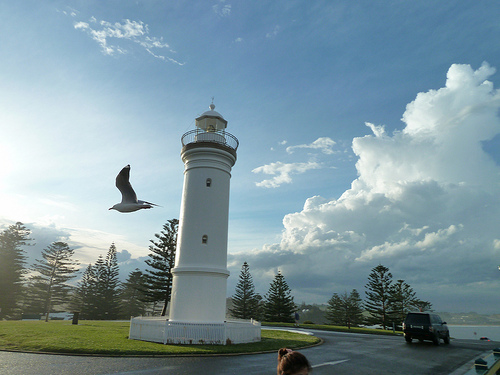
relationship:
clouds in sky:
[42, 1, 204, 88] [7, 52, 495, 276]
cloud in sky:
[254, 156, 321, 198] [50, 19, 468, 93]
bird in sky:
[108, 164, 164, 213] [1, 0, 498, 310]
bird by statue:
[108, 164, 164, 213] [130, 93, 261, 344]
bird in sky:
[108, 164, 164, 213] [268, 31, 388, 128]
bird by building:
[108, 164, 164, 213] [128, 96, 262, 345]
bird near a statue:
[108, 164, 164, 213] [130, 93, 261, 344]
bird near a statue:
[108, 162, 155, 214] [122, 80, 269, 347]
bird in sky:
[108, 162, 155, 214] [1, 0, 498, 310]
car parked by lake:
[403, 311, 451, 345] [358, 324, 499, 342]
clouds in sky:
[382, 71, 497, 310] [8, 10, 498, 233]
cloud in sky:
[250, 161, 321, 187] [8, 10, 498, 233]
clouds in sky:
[56, 7, 186, 65] [8, 10, 498, 233]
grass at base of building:
[2, 317, 319, 354] [128, 96, 262, 345]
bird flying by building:
[108, 164, 164, 213] [128, 96, 262, 345]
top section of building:
[181, 97, 241, 160] [128, 96, 262, 345]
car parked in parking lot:
[403, 311, 451, 345] [0, 311, 482, 373]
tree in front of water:
[366, 261, 397, 336] [449, 320, 495, 344]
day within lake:
[4, 3, 418, 334] [344, 301, 495, 365]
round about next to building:
[92, 303, 382, 374] [128, 96, 262, 345]